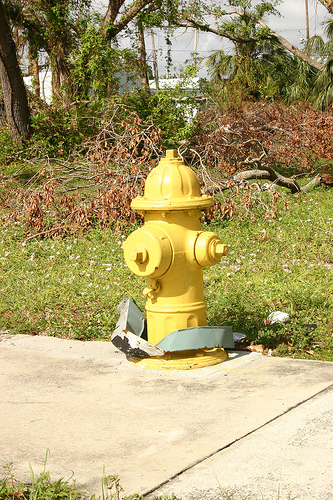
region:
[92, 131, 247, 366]
a yellow fire hydrant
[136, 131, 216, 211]
top of a fire hydrant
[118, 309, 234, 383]
base of a fire hydrant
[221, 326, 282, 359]
shadows of a hydrant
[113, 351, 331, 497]
creases on the pavement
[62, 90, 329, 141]
trees and bushes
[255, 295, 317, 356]
garbage on the grassy field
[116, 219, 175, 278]
parts of a fire hydrant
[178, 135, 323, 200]
a tree branch on grass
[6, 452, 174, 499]
bushes near side of road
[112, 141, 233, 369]
fire hydrant on ground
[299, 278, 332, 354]
grass on the ground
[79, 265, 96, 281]
white flowers in the grass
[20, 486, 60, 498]
green grass on side of pavement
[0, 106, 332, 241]
tree branch on the ground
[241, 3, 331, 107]
branch of standing tree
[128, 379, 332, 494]
line in the sidewalk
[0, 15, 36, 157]
the bark of the tree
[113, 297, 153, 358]
trash on the ground near hydrant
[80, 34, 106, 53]
leaves on the trees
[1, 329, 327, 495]
gray cement sectioned sidewalk near overgrown grass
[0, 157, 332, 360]
overgrown green grass by sidewalk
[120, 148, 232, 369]
yellow fire hydrant mounted on a sidewalk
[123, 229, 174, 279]
nozzle of a yellow fire hydrant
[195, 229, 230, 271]
nozzle of a yellow fire hydrant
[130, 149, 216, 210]
domed top of a yellow fire hydrant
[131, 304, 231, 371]
round base of a yellow fire hydrant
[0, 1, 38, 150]
dark gray tree trunk in overgrown area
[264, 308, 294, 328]
white litter laying on overgrown green grass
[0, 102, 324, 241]
broken off branch laying on the gorund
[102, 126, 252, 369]
hydrant on the ground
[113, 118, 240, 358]
the hydrant is yellow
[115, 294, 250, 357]
green object on the hydrant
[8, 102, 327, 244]
orange leaves on branch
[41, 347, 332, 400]
black spots on the ground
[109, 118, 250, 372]
sun shining on the hydrant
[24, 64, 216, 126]
building behind the trees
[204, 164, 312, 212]
tree branch is curved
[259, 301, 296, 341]
plastic object in grass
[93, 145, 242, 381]
A yellow fire hydrant in the sidewalk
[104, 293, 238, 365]
A piece of scrap metal around the hydrant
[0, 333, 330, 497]
A concrete sidewalk surrounded by grass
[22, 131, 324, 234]
A downed tree branch behind the hydrant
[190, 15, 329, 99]
A tree that is leaning over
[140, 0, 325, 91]
Telephone poles behind the trees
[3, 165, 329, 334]
Grassy area behind the hydrant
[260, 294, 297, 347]
A piece of trash near the hydrant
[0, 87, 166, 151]
More downed branches at the base of some trees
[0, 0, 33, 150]
A large still standing tree